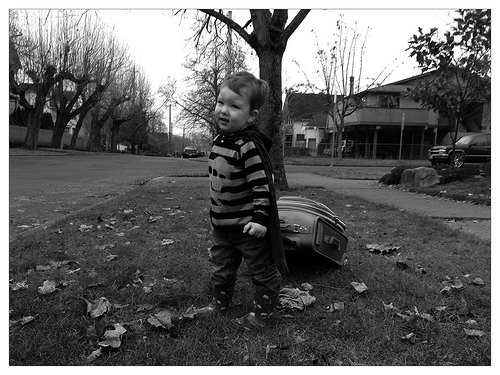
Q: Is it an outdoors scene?
A: Yes, it is outdoors.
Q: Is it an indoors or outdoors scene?
A: It is outdoors.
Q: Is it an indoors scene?
A: No, it is outdoors.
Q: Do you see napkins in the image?
A: No, there are no napkins.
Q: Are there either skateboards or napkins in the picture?
A: No, there are no napkins or skateboards.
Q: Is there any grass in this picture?
A: Yes, there is grass.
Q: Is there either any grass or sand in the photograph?
A: Yes, there is grass.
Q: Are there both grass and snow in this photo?
A: No, there is grass but no snow.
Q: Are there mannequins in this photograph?
A: No, there are no mannequins.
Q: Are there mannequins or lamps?
A: No, there are no mannequins or lamps.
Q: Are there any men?
A: No, there are no men.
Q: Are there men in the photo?
A: No, there are no men.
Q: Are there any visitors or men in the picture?
A: No, there are no men or visitors.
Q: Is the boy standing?
A: Yes, the boy is standing.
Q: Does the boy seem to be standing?
A: Yes, the boy is standing.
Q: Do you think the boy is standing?
A: Yes, the boy is standing.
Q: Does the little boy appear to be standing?
A: Yes, the boy is standing.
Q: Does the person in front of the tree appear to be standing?
A: Yes, the boy is standing.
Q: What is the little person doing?
A: The boy is standing.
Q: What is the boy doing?
A: The boy is standing.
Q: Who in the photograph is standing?
A: The boy is standing.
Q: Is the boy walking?
A: No, the boy is standing.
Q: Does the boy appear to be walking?
A: No, the boy is standing.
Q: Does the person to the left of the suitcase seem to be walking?
A: No, the boy is standing.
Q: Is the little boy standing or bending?
A: The boy is standing.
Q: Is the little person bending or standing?
A: The boy is standing.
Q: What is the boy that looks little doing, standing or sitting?
A: The boy is standing.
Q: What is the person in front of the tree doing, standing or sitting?
A: The boy is standing.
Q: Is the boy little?
A: Yes, the boy is little.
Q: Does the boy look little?
A: Yes, the boy is little.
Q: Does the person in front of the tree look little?
A: Yes, the boy is little.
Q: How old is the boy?
A: The boy is little.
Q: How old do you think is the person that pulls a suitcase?
A: The boy is little.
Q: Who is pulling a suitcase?
A: The boy is pulling a suitcase.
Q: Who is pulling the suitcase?
A: The boy is pulling a suitcase.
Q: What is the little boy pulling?
A: The boy is pulling a suitcase.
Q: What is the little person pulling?
A: The boy is pulling a suitcase.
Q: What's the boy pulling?
A: The boy is pulling a suitcase.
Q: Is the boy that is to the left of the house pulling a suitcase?
A: Yes, the boy is pulling a suitcase.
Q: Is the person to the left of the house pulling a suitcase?
A: Yes, the boy is pulling a suitcase.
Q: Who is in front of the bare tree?
A: The boy is in front of the tree.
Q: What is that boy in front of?
A: The boy is in front of the tree.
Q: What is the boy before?
A: The boy is in front of the tree.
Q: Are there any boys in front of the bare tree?
A: Yes, there is a boy in front of the tree.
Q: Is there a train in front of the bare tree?
A: No, there is a boy in front of the tree.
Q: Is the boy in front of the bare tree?
A: Yes, the boy is in front of the tree.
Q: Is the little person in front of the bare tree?
A: Yes, the boy is in front of the tree.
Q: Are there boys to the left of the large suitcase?
A: Yes, there is a boy to the left of the suitcase.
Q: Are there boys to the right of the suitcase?
A: No, the boy is to the left of the suitcase.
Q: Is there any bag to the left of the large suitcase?
A: No, there is a boy to the left of the suitcase.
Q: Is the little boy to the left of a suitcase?
A: Yes, the boy is to the left of a suitcase.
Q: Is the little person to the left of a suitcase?
A: Yes, the boy is to the left of a suitcase.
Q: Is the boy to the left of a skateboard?
A: No, the boy is to the left of a suitcase.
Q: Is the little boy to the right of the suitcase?
A: No, the boy is to the left of the suitcase.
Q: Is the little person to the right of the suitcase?
A: No, the boy is to the left of the suitcase.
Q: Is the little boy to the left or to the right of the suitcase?
A: The boy is to the left of the suitcase.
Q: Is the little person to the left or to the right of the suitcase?
A: The boy is to the left of the suitcase.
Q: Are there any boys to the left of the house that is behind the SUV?
A: Yes, there is a boy to the left of the house.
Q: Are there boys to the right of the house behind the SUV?
A: No, the boy is to the left of the house.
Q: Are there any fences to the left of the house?
A: No, there is a boy to the left of the house.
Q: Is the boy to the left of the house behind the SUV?
A: Yes, the boy is to the left of the house.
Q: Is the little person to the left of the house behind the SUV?
A: Yes, the boy is to the left of the house.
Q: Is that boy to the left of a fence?
A: No, the boy is to the left of the house.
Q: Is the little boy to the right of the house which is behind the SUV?
A: No, the boy is to the left of the house.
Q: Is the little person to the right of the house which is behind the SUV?
A: No, the boy is to the left of the house.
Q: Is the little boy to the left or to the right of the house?
A: The boy is to the left of the house.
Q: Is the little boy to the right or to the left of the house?
A: The boy is to the left of the house.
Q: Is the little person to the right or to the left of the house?
A: The boy is to the left of the house.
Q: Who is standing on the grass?
A: The boy is standing on the grass.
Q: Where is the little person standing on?
A: The boy is standing on the grass.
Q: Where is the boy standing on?
A: The boy is standing on the grass.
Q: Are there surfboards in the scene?
A: No, there are no surfboards.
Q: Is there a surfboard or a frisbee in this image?
A: No, there are no surfboards or frisbees.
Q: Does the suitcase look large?
A: Yes, the suitcase is large.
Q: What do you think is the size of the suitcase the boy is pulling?
A: The suitcase is large.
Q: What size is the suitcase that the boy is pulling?
A: The suitcase is large.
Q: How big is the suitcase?
A: The suitcase is large.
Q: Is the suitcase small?
A: No, the suitcase is large.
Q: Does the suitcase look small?
A: No, the suitcase is large.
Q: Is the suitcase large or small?
A: The suitcase is large.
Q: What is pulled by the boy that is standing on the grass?
A: The suitcase is pulled by the boy.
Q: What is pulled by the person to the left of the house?
A: The suitcase is pulled by the boy.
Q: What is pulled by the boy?
A: The suitcase is pulled by the boy.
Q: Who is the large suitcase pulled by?
A: The suitcase is pulled by the boy.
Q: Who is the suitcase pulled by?
A: The suitcase is pulled by the boy.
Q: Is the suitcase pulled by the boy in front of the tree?
A: Yes, the suitcase is pulled by the boy.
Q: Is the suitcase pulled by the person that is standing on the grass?
A: Yes, the suitcase is pulled by the boy.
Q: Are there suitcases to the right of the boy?
A: Yes, there is a suitcase to the right of the boy.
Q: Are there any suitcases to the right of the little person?
A: Yes, there is a suitcase to the right of the boy.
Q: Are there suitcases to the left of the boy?
A: No, the suitcase is to the right of the boy.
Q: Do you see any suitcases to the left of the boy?
A: No, the suitcase is to the right of the boy.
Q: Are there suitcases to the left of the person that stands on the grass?
A: No, the suitcase is to the right of the boy.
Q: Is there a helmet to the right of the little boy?
A: No, there is a suitcase to the right of the boy.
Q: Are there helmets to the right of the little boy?
A: No, there is a suitcase to the right of the boy.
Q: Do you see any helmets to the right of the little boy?
A: No, there is a suitcase to the right of the boy.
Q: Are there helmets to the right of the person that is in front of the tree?
A: No, there is a suitcase to the right of the boy.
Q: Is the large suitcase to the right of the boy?
A: Yes, the suitcase is to the right of the boy.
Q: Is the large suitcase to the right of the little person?
A: Yes, the suitcase is to the right of the boy.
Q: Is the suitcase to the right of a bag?
A: No, the suitcase is to the right of the boy.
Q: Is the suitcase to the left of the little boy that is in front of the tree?
A: No, the suitcase is to the right of the boy.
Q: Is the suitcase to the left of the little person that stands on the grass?
A: No, the suitcase is to the right of the boy.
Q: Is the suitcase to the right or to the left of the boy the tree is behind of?
A: The suitcase is to the right of the boy.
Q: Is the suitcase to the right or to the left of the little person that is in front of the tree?
A: The suitcase is to the right of the boy.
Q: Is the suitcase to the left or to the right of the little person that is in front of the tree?
A: The suitcase is to the right of the boy.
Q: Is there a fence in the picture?
A: No, there are no fences.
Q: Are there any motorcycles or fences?
A: No, there are no fences or motorcycles.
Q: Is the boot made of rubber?
A: Yes, the boot is made of rubber.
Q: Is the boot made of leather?
A: No, the boot is made of rubber.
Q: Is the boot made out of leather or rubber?
A: The boot is made of rubber.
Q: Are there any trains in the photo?
A: No, there are no trains.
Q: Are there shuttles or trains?
A: No, there are no trains or shuttles.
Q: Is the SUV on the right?
A: Yes, the SUV is on the right of the image.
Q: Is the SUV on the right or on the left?
A: The SUV is on the right of the image.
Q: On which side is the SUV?
A: The SUV is on the right of the image.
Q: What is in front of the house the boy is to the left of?
A: The SUV is in front of the house.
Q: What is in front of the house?
A: The SUV is in front of the house.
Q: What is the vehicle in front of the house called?
A: The vehicle is a SUV.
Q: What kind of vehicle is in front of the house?
A: The vehicle is a SUV.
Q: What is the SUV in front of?
A: The SUV is in front of the house.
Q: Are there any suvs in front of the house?
A: Yes, there is a SUV in front of the house.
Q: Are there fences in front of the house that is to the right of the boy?
A: No, there is a SUV in front of the house.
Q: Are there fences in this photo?
A: No, there are no fences.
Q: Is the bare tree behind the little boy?
A: Yes, the tree is behind the boy.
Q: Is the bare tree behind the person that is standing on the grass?
A: Yes, the tree is behind the boy.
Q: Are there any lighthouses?
A: No, there are no lighthouses.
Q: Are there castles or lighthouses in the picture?
A: No, there are no lighthouses or castles.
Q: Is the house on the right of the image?
A: Yes, the house is on the right of the image.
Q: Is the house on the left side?
A: No, the house is on the right of the image.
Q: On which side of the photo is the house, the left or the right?
A: The house is on the right of the image.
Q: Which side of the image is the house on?
A: The house is on the right of the image.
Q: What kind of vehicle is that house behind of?
A: The house is behind the SUV.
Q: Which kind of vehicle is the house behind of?
A: The house is behind the SUV.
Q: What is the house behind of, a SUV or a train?
A: The house is behind a SUV.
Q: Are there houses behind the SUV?
A: Yes, there is a house behind the SUV.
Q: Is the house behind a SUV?
A: Yes, the house is behind a SUV.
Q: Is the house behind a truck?
A: No, the house is behind a SUV.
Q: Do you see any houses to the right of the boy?
A: Yes, there is a house to the right of the boy.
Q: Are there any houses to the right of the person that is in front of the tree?
A: Yes, there is a house to the right of the boy.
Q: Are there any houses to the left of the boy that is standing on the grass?
A: No, the house is to the right of the boy.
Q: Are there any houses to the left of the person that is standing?
A: No, the house is to the right of the boy.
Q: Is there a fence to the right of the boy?
A: No, there is a house to the right of the boy.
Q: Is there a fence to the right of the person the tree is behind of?
A: No, there is a house to the right of the boy.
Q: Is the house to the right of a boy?
A: Yes, the house is to the right of a boy.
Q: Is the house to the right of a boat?
A: No, the house is to the right of a boy.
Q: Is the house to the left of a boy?
A: No, the house is to the right of a boy.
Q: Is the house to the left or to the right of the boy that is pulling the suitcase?
A: The house is to the right of the boy.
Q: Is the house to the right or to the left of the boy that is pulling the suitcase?
A: The house is to the right of the boy.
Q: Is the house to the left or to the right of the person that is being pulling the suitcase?
A: The house is to the right of the boy.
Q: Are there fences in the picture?
A: No, there are no fences.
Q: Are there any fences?
A: No, there are no fences.